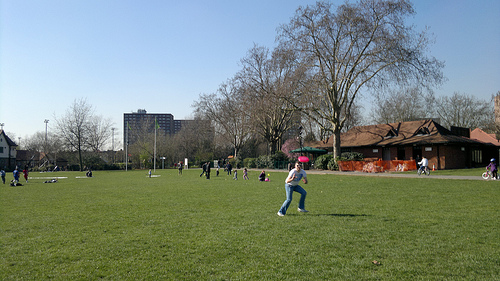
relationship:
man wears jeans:
[272, 162, 314, 221] [278, 184, 309, 210]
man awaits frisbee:
[272, 162, 314, 221] [296, 153, 310, 164]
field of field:
[0, 167, 499, 281] [0, 168, 499, 281]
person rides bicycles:
[414, 155, 432, 176] [416, 161, 432, 176]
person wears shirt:
[414, 155, 432, 176] [414, 159, 430, 167]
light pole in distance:
[43, 118, 52, 147] [1, 0, 328, 168]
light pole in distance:
[110, 122, 116, 156] [1, 0, 328, 168]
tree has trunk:
[241, 0, 452, 185] [328, 92, 342, 173]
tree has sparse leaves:
[241, 0, 452, 185] [267, 0, 449, 93]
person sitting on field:
[84, 167, 94, 179] [0, 168, 499, 281]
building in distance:
[119, 107, 217, 171] [1, 0, 328, 168]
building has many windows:
[119, 107, 217, 171] [126, 114, 208, 148]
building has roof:
[298, 112, 499, 175] [303, 112, 499, 149]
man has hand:
[272, 162, 314, 221] [290, 171, 298, 182]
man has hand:
[272, 162, 314, 221] [302, 177, 310, 185]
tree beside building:
[241, 0, 452, 185] [298, 112, 499, 175]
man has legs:
[272, 162, 314, 221] [281, 190, 310, 209]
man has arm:
[272, 162, 314, 221] [282, 170, 299, 185]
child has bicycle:
[478, 155, 499, 182] [478, 170, 499, 184]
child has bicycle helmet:
[478, 155, 499, 182] [489, 158, 495, 164]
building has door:
[298, 112, 499, 175] [410, 148, 421, 170]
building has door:
[298, 112, 499, 175] [397, 148, 406, 162]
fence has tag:
[338, 156, 418, 175] [391, 162, 408, 174]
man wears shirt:
[272, 162, 314, 221] [284, 169, 309, 186]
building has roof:
[1, 127, 19, 171] [0, 127, 19, 147]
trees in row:
[180, 1, 449, 170] [226, 153, 343, 170]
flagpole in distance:
[122, 120, 133, 172] [1, 0, 328, 168]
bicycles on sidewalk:
[410, 153, 500, 182] [191, 164, 499, 181]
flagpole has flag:
[122, 120, 133, 172] [123, 119, 135, 134]